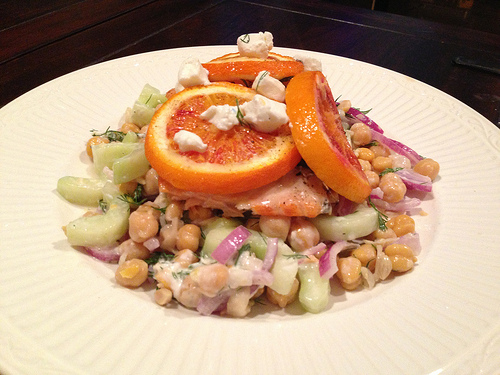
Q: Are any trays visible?
A: No, there are no trays.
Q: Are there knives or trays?
A: No, there are no trays or knives.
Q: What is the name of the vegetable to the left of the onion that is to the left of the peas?
A: The vegetable is a celery.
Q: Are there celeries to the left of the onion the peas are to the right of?
A: Yes, there is a celery to the left of the onion.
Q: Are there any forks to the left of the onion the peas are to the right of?
A: No, there is a celery to the left of the onion.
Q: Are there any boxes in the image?
A: No, there are no boxes.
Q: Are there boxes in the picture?
A: No, there are no boxes.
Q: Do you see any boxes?
A: No, there are no boxes.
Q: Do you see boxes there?
A: No, there are no boxes.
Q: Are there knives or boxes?
A: No, there are no boxes or knives.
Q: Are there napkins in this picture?
A: No, there are no napkins.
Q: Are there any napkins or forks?
A: No, there are no napkins or forks.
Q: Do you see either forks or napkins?
A: No, there are no napkins or forks.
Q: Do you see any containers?
A: No, there are no containers.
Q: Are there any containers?
A: No, there are no containers.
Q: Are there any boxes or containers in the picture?
A: No, there are no containers or boxes.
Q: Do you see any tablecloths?
A: No, there are no tablecloths.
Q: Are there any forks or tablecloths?
A: No, there are no tablecloths or forks.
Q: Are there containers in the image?
A: No, there are no containers.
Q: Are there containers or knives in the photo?
A: No, there are no containers or knives.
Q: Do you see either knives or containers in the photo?
A: No, there are no containers or knives.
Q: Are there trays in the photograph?
A: No, there are no trays.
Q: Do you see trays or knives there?
A: No, there are no trays or knives.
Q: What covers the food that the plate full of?
A: The sauce covers the food.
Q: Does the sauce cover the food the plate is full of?
A: Yes, the sauce covers the food.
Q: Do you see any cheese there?
A: Yes, there is cheese.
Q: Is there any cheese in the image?
A: Yes, there is cheese.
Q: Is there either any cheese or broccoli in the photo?
A: Yes, there is cheese.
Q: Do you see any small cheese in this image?
A: Yes, there is small cheese.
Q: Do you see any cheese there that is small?
A: Yes, there is cheese that is small.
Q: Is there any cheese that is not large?
A: Yes, there is small cheese.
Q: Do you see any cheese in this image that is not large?
A: Yes, there is small cheese.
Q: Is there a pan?
A: No, there are no pans.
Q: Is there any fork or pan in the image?
A: No, there are no pans or forks.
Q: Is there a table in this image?
A: Yes, there is a table.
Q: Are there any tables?
A: Yes, there is a table.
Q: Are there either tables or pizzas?
A: Yes, there is a table.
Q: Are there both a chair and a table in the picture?
A: No, there is a table but no chairs.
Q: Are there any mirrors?
A: No, there are no mirrors.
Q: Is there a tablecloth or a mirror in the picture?
A: No, there are no mirrors or tablecloths.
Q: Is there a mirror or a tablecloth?
A: No, there are no mirrors or tablecloths.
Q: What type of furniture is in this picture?
A: The furniture is a table.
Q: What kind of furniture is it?
A: The piece of furniture is a table.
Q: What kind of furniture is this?
A: This is a table.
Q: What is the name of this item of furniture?
A: This is a table.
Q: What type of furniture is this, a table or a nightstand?
A: This is a table.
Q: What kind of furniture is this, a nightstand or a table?
A: This is a table.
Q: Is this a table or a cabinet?
A: This is a table.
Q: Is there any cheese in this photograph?
A: Yes, there is cheese.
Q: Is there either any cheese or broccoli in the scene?
A: Yes, there is cheese.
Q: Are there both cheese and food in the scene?
A: Yes, there are both cheese and food.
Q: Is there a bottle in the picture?
A: No, there are no bottles.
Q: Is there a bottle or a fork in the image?
A: No, there are no bottles or forks.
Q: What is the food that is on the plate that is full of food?
A: The food is cheese.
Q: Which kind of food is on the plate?
A: The food is cheese.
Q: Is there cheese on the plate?
A: Yes, there is cheese on the plate.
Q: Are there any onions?
A: Yes, there is an onion.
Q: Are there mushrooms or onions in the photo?
A: Yes, there is an onion.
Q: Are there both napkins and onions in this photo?
A: No, there is an onion but no napkins.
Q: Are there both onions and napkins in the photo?
A: No, there is an onion but no napkins.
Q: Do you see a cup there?
A: No, there are no cups.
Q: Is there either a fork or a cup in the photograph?
A: No, there are no cups or forks.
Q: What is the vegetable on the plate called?
A: The vegetable is an onion.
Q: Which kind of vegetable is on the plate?
A: The vegetable is an onion.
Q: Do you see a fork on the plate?
A: No, there is an onion on the plate.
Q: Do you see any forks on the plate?
A: No, there is an onion on the plate.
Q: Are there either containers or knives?
A: No, there are no containers or knives.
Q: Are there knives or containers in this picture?
A: No, there are no containers or knives.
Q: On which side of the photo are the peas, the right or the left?
A: The peas are on the right of the image.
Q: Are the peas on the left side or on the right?
A: The peas are on the right of the image.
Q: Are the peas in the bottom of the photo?
A: Yes, the peas are in the bottom of the image.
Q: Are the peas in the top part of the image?
A: No, the peas are in the bottom of the image.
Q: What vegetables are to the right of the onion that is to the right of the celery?
A: The vegetables are peas.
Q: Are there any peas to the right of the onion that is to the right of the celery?
A: Yes, there are peas to the right of the onion.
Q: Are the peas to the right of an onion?
A: Yes, the peas are to the right of an onion.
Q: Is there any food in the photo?
A: Yes, there is food.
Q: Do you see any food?
A: Yes, there is food.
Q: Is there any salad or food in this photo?
A: Yes, there is food.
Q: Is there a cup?
A: No, there are no cups.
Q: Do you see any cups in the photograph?
A: No, there are no cups.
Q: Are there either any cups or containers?
A: No, there are no cups or containers.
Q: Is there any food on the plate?
A: Yes, there is food on the plate.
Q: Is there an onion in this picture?
A: Yes, there is an onion.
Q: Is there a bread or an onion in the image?
A: Yes, there is an onion.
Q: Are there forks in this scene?
A: No, there are no forks.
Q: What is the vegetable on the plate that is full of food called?
A: The vegetable is an onion.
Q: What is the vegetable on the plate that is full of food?
A: The vegetable is an onion.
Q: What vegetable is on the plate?
A: The vegetable is an onion.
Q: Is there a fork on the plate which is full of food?
A: No, there is an onion on the plate.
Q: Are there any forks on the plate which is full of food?
A: No, there is an onion on the plate.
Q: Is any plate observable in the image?
A: Yes, there is a plate.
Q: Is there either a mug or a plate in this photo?
A: Yes, there is a plate.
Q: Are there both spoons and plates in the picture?
A: No, there is a plate but no spoons.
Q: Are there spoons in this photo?
A: No, there are no spoons.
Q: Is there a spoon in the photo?
A: No, there are no spoons.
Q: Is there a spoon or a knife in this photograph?
A: No, there are no spoons or knives.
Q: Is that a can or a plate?
A: That is a plate.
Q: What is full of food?
A: The plate is full of food.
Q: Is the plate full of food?
A: Yes, the plate is full of food.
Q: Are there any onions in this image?
A: Yes, there is an onion.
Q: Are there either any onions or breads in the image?
A: Yes, there is an onion.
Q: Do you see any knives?
A: No, there are no knives.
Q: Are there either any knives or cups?
A: No, there are no knives or cups.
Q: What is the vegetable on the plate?
A: The vegetable is an onion.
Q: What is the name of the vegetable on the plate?
A: The vegetable is an onion.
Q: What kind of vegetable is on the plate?
A: The vegetable is an onion.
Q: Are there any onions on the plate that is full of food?
A: Yes, there is an onion on the plate.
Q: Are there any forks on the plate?
A: No, there is an onion on the plate.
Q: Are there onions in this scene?
A: Yes, there is an onion.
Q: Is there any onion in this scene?
A: Yes, there is an onion.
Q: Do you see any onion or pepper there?
A: Yes, there is an onion.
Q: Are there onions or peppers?
A: Yes, there is an onion.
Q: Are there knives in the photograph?
A: No, there are no knives.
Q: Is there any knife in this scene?
A: No, there are no knives.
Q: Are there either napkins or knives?
A: No, there are no knives or napkins.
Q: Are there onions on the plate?
A: Yes, there is an onion on the plate.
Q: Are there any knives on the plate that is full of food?
A: No, there is an onion on the plate.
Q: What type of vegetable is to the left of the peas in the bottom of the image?
A: The vegetable is an onion.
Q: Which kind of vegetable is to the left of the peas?
A: The vegetable is an onion.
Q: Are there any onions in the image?
A: Yes, there is an onion.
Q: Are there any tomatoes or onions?
A: Yes, there is an onion.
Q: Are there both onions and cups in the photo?
A: No, there is an onion but no cups.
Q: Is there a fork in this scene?
A: No, there are no forks.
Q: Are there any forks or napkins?
A: No, there are no forks or napkins.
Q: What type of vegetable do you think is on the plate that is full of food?
A: The vegetable is an onion.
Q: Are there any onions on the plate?
A: Yes, there is an onion on the plate.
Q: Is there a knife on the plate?
A: No, there is an onion on the plate.